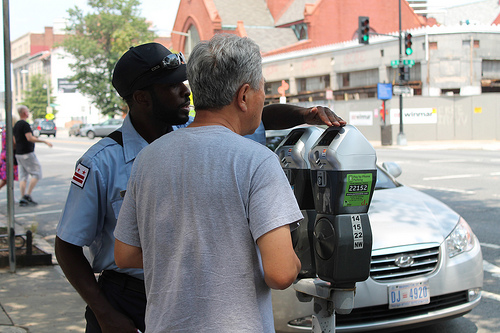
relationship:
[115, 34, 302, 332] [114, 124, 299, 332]
man wears tshirt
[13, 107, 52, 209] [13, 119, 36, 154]
man wears shirt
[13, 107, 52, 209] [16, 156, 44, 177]
man wears shorts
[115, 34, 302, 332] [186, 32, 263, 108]
man has hair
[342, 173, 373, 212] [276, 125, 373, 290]
sticker on meter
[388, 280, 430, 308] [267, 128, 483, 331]
license on car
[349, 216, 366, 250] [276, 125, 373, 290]
sticker on meter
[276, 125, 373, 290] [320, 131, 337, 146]
meter has screen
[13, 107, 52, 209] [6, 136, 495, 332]
man in street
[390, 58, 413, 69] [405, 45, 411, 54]
sign below light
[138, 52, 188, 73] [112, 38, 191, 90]
sunglasses on hat